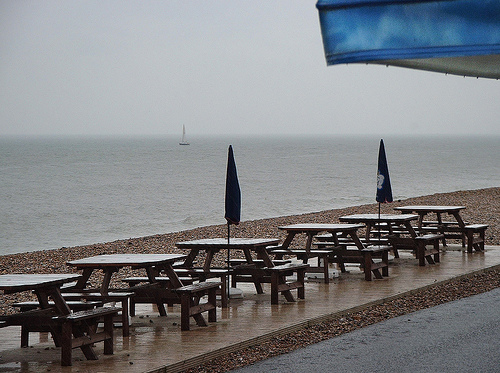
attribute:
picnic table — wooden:
[393, 198, 492, 252]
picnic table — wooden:
[320, 203, 442, 265]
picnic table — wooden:
[276, 219, 390, 281]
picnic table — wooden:
[65, 249, 219, 329]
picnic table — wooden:
[163, 230, 312, 306]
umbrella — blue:
[373, 136, 390, 246]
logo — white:
[376, 168, 383, 191]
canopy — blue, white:
[365, 139, 394, 231]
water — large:
[50, 144, 132, 221]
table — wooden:
[0, 273, 112, 367]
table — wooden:
[67, 252, 220, 327]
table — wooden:
[172, 235, 309, 308]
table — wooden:
[281, 217, 392, 287]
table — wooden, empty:
[345, 205, 440, 270]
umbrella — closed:
[219, 142, 244, 227]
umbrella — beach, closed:
[223, 142, 248, 301]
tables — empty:
[3, 195, 488, 362]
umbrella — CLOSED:
[210, 137, 245, 294]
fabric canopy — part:
[316, 0, 498, 78]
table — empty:
[390, 192, 480, 259]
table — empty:
[267, 213, 394, 284]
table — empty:
[173, 231, 305, 306]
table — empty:
[62, 247, 222, 325]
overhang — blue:
[317, 0, 498, 79]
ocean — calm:
[0, 135, 500, 200]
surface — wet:
[9, 188, 498, 369]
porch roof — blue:
[318, 0, 497, 86]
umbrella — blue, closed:
[367, 126, 398, 210]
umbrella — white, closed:
[224, 144, 243, 224]